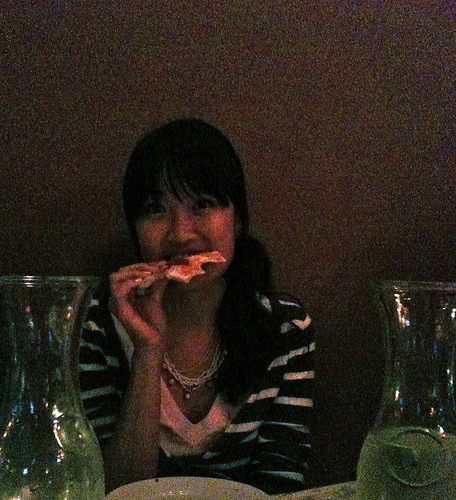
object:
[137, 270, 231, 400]
necklace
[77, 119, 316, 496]
woman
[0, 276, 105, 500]
vase